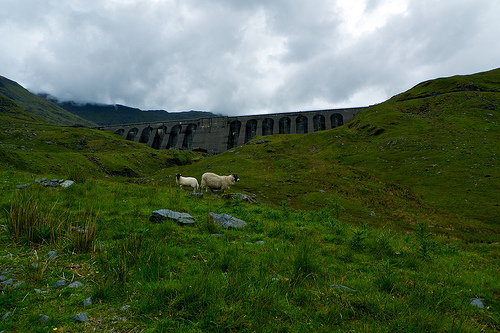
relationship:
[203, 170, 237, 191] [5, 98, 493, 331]
sheep in field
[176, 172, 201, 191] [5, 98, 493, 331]
sheep in field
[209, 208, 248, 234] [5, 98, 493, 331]
rocks in field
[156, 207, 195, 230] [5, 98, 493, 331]
rocks in field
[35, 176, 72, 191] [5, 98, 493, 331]
rocks in field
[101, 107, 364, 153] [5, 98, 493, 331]
bridge over field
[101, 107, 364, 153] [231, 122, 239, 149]
bridge with arches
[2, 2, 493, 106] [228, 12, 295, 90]
sky with clouds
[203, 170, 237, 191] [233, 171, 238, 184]
sheep with head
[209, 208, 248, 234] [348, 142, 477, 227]
rocks on grass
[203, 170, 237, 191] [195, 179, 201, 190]
sheep with tail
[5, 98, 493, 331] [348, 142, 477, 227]
field with grass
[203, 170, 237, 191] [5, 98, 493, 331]
sheep on field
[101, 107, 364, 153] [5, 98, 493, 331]
bridge behhind field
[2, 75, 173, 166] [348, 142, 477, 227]
hill covered in grass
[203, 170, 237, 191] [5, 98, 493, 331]
sheep standing in field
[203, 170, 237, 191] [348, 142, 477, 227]
sheep standing in grass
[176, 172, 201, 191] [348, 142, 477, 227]
sheep standing in grass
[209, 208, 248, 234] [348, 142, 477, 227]
rocks in grass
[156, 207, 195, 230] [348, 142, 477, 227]
rocks in grass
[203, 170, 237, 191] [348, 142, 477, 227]
sheep in grass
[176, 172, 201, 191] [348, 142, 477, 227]
sheep in grass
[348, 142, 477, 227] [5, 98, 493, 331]
grass in field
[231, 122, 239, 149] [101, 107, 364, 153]
arches on bridge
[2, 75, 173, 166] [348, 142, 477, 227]
hill with grass